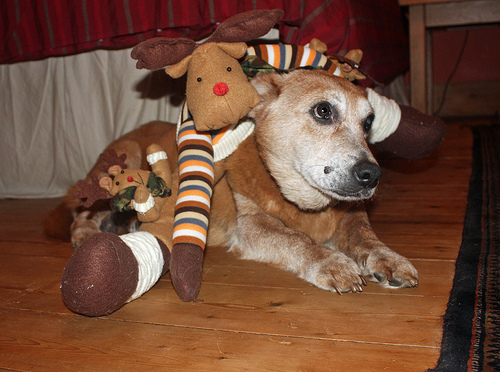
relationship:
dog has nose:
[199, 60, 387, 280] [355, 148, 389, 179]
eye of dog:
[306, 76, 358, 122] [199, 60, 387, 280]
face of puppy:
[220, 57, 408, 203] [199, 60, 387, 280]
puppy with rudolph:
[199, 60, 387, 280] [117, 17, 282, 169]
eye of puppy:
[306, 76, 358, 122] [199, 60, 387, 280]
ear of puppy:
[215, 51, 274, 114] [61, 24, 402, 283]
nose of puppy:
[355, 148, 389, 179] [61, 24, 402, 283]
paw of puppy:
[333, 253, 427, 278] [199, 60, 387, 280]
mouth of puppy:
[312, 172, 375, 224] [61, 24, 402, 283]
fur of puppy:
[230, 174, 270, 202] [61, 24, 402, 283]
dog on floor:
[199, 60, 387, 280] [394, 166, 452, 236]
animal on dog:
[117, 17, 282, 169] [199, 60, 387, 280]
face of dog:
[220, 57, 408, 203] [199, 60, 387, 280]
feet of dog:
[268, 222, 447, 368] [199, 60, 387, 280]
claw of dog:
[278, 236, 433, 334] [199, 60, 387, 280]